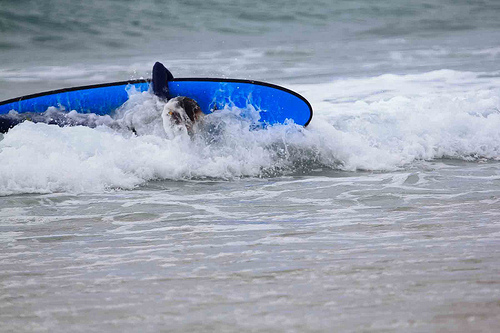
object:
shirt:
[151, 62, 171, 107]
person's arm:
[150, 61, 174, 96]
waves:
[1, 1, 500, 333]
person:
[0, 61, 221, 147]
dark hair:
[166, 98, 200, 124]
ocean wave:
[220, 121, 317, 181]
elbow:
[152, 61, 168, 73]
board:
[0, 77, 312, 134]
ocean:
[0, 0, 500, 332]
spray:
[1, 70, 499, 197]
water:
[0, 0, 499, 333]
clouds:
[0, 0, 499, 48]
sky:
[0, 0, 499, 28]